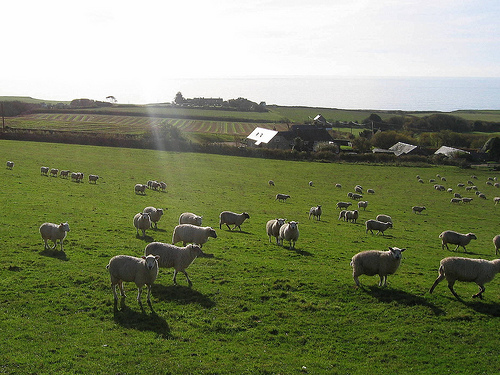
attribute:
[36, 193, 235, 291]
sheep — standing, looking, running, white, flock, herd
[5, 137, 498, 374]
pasture — green, grassy, covered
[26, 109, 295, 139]
field — distant, plowed, vast, green, cultivated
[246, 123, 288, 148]
building — distant, country style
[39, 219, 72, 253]
sheep — little, white, walking, watching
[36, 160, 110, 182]
sheep — walking, group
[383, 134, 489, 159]
buildings — distant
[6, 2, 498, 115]
sky — cloudy, light blue, clear, bright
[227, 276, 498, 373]
grass — trimmed, green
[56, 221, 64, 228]
ear — black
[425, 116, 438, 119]
leaves — green